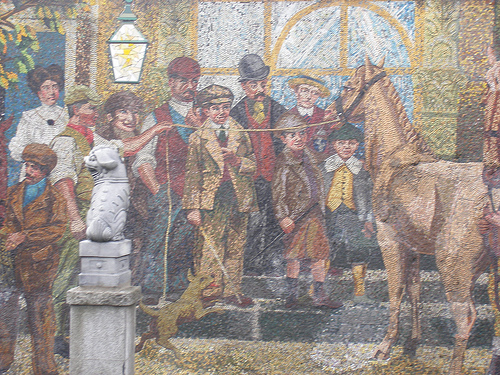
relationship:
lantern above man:
[104, 2, 149, 85] [101, 91, 145, 140]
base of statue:
[64, 238, 142, 374] [66, 146, 145, 374]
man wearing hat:
[138, 59, 206, 300] [168, 55, 202, 80]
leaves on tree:
[37, 1, 102, 37] [0, 2, 100, 105]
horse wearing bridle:
[322, 56, 499, 373] [333, 70, 387, 126]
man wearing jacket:
[0, 142, 70, 374] [0, 181, 72, 289]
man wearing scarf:
[0, 142, 70, 374] [22, 180, 48, 209]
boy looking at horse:
[320, 123, 378, 308] [322, 56, 499, 373]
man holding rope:
[50, 80, 175, 360] [156, 120, 344, 307]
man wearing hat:
[229, 53, 291, 275] [237, 52, 270, 82]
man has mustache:
[229, 53, 291, 275] [254, 91, 268, 100]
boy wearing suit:
[271, 116, 340, 307] [274, 149, 328, 258]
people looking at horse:
[16, 51, 372, 302] [322, 56, 499, 373]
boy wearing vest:
[321, 123, 378, 309] [328, 166, 355, 215]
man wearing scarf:
[50, 80, 175, 360] [69, 123, 95, 149]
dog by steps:
[135, 268, 225, 356] [189, 266, 497, 347]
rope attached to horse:
[156, 120, 344, 307] [322, 56, 499, 373]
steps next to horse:
[189, 266, 497, 347] [322, 56, 499, 373]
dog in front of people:
[135, 268, 225, 356] [16, 51, 372, 302]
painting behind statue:
[1, 1, 499, 371] [66, 146, 145, 374]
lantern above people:
[104, 2, 149, 85] [16, 51, 372, 302]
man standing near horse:
[281, 69, 334, 144] [322, 56, 499, 373]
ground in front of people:
[134, 336, 499, 372] [16, 51, 372, 302]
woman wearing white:
[8, 62, 70, 178] [10, 107, 69, 173]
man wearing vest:
[138, 59, 206, 300] [152, 103, 188, 196]